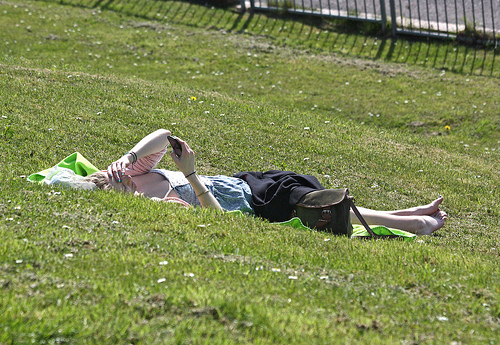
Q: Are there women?
A: Yes, there is a woman.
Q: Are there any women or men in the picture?
A: Yes, there is a woman.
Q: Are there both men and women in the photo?
A: No, there is a woman but no men.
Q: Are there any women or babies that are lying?
A: Yes, the woman is lying.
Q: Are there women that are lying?
A: Yes, there is a woman that is lying.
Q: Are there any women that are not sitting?
A: Yes, there is a woman that is lying.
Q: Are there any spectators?
A: No, there are no spectators.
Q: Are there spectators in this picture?
A: No, there are no spectators.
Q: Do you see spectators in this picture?
A: No, there are no spectators.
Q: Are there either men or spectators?
A: No, there are no spectators or men.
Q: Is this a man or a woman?
A: This is a woman.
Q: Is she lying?
A: Yes, the woman is lying.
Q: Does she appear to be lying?
A: Yes, the woman is lying.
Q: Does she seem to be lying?
A: Yes, the woman is lying.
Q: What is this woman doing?
A: The woman is lying.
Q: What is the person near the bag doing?
A: The woman is lying.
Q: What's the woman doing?
A: The woman is lying.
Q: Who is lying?
A: The woman is lying.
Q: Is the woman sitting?
A: No, the woman is lying.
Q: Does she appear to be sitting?
A: No, the woman is lying.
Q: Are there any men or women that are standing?
A: No, there is a woman but she is lying.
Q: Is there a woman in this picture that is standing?
A: No, there is a woman but she is lying.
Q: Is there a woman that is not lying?
A: No, there is a woman but she is lying.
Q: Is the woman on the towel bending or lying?
A: The woman is lying.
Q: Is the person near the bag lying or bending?
A: The woman is lying.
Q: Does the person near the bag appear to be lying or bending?
A: The woman is lying.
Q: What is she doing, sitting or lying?
A: The woman is lying.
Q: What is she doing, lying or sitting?
A: The woman is lying.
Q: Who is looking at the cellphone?
A: The woman is looking at the cellphone.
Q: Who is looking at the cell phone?
A: The woman is looking at the cellphone.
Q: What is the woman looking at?
A: The woman is looking at the mobile phone.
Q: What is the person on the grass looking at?
A: The woman is looking at the mobile phone.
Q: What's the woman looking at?
A: The woman is looking at the mobile phone.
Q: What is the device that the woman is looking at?
A: The device is a cell phone.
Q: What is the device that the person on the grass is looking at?
A: The device is a cell phone.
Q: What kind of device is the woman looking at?
A: The woman is looking at the cell phone.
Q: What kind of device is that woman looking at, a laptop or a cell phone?
A: The woman is looking at a cell phone.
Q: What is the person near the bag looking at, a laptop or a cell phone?
A: The woman is looking at a cell phone.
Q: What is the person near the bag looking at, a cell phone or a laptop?
A: The woman is looking at a cell phone.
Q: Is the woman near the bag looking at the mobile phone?
A: Yes, the woman is looking at the mobile phone.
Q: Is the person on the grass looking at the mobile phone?
A: Yes, the woman is looking at the mobile phone.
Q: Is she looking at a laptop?
A: No, the woman is looking at the mobile phone.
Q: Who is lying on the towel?
A: The woman is lying on the towel.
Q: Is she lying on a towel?
A: Yes, the woman is lying on a towel.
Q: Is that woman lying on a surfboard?
A: No, the woman is lying on a towel.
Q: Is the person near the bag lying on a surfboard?
A: No, the woman is lying on a towel.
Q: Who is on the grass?
A: The woman is on the grass.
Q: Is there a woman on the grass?
A: Yes, there is a woman on the grass.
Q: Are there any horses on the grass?
A: No, there is a woman on the grass.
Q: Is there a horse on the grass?
A: No, there is a woman on the grass.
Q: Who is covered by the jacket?
A: The woman is covered by the jacket.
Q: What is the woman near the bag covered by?
A: The woman is covered by the jacket.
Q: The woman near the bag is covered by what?
A: The woman is covered by the jacket.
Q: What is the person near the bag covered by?
A: The woman is covered by the jacket.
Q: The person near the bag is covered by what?
A: The woman is covered by the jacket.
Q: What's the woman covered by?
A: The woman is covered by the jacket.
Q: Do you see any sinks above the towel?
A: No, there is a woman above the towel.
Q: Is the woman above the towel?
A: Yes, the woman is above the towel.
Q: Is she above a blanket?
A: No, the woman is above the towel.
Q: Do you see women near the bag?
A: Yes, there is a woman near the bag.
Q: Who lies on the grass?
A: The woman lies on the grass.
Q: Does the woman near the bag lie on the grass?
A: Yes, the woman lies on the grass.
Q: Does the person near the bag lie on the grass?
A: Yes, the woman lies on the grass.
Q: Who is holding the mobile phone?
A: The woman is holding the mobile phone.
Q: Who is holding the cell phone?
A: The woman is holding the mobile phone.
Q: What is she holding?
A: The woman is holding the cell phone.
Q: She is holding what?
A: The woman is holding the cell phone.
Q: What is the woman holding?
A: The woman is holding the cell phone.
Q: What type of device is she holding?
A: The woman is holding the cellphone.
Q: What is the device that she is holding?
A: The device is a cell phone.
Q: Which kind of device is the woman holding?
A: The woman is holding the cellphone.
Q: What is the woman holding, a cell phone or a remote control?
A: The woman is holding a cell phone.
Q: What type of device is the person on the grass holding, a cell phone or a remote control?
A: The woman is holding a cell phone.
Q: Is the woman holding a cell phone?
A: Yes, the woman is holding a cell phone.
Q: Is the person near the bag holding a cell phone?
A: Yes, the woman is holding a cell phone.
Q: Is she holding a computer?
A: No, the woman is holding a cell phone.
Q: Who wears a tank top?
A: The woman wears a tank top.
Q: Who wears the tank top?
A: The woman wears a tank top.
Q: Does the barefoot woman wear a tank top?
A: Yes, the woman wears a tank top.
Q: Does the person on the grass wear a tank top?
A: Yes, the woman wears a tank top.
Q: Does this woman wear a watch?
A: No, the woman wears a tank top.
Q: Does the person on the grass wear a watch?
A: No, the woman wears a tank top.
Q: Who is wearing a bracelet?
A: The woman is wearing a bracelet.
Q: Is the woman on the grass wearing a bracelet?
A: Yes, the woman is wearing a bracelet.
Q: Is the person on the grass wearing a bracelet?
A: Yes, the woman is wearing a bracelet.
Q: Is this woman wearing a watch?
A: No, the woman is wearing a bracelet.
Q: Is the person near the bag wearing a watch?
A: No, the woman is wearing a bracelet.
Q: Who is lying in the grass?
A: The woman is lying in the grass.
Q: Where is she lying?
A: The woman is lying in the grass.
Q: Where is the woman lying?
A: The woman is lying in the grass.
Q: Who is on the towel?
A: The woman is on the towel.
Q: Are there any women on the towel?
A: Yes, there is a woman on the towel.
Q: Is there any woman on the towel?
A: Yes, there is a woman on the towel.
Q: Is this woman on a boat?
A: No, the woman is on the towel.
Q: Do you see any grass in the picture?
A: Yes, there is grass.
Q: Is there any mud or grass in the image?
A: Yes, there is grass.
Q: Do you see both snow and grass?
A: No, there is grass but no snow.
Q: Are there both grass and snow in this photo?
A: No, there is grass but no snow.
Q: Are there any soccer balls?
A: No, there are no soccer balls.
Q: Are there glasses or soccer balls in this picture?
A: No, there are no soccer balls or glasses.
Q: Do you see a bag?
A: Yes, there is a bag.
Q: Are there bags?
A: Yes, there is a bag.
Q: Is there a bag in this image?
A: Yes, there is a bag.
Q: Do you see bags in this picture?
A: Yes, there is a bag.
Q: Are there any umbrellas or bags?
A: Yes, there is a bag.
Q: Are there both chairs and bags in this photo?
A: No, there is a bag but no chairs.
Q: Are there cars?
A: No, there are no cars.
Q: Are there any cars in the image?
A: No, there are no cars.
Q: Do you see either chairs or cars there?
A: No, there are no cars or chairs.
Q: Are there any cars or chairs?
A: No, there are no cars or chairs.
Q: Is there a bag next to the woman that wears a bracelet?
A: Yes, there is a bag next to the woman.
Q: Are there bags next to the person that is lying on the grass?
A: Yes, there is a bag next to the woman.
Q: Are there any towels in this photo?
A: Yes, there is a towel.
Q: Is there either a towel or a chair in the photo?
A: Yes, there is a towel.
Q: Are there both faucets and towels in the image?
A: No, there is a towel but no faucets.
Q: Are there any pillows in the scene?
A: No, there are no pillows.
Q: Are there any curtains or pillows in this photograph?
A: No, there are no pillows or curtains.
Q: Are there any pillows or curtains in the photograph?
A: No, there are no pillows or curtains.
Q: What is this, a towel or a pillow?
A: This is a towel.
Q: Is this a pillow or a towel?
A: This is a towel.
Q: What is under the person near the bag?
A: The towel is under the woman.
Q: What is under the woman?
A: The towel is under the woman.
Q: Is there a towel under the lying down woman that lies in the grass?
A: Yes, there is a towel under the woman.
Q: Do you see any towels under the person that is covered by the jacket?
A: Yes, there is a towel under the woman.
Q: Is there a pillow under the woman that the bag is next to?
A: No, there is a towel under the woman.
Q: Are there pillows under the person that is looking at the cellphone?
A: No, there is a towel under the woman.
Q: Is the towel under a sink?
A: No, the towel is under a woman.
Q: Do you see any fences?
A: Yes, there is a fence.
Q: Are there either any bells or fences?
A: Yes, there is a fence.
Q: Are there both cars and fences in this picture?
A: No, there is a fence but no cars.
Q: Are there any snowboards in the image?
A: No, there are no snowboards.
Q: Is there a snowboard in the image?
A: No, there are no snowboards.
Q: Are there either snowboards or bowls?
A: No, there are no snowboards or bowls.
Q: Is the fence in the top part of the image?
A: Yes, the fence is in the top of the image.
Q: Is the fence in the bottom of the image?
A: No, the fence is in the top of the image.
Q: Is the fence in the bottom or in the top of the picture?
A: The fence is in the top of the image.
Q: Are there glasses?
A: No, there are no glasses.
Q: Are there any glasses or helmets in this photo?
A: No, there are no glasses or helmets.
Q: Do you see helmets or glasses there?
A: No, there are no glasses or helmets.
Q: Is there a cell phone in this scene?
A: Yes, there is a cell phone.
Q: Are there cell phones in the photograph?
A: Yes, there is a cell phone.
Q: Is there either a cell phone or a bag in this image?
A: Yes, there is a cell phone.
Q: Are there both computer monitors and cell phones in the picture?
A: No, there is a cell phone but no computer monitors.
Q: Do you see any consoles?
A: No, there are no consoles.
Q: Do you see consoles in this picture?
A: No, there are no consoles.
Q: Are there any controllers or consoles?
A: No, there are no consoles or controllers.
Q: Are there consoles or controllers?
A: No, there are no consoles or controllers.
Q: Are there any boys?
A: No, there are no boys.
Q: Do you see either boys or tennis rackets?
A: No, there are no boys or tennis rackets.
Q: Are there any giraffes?
A: No, there are no giraffes.